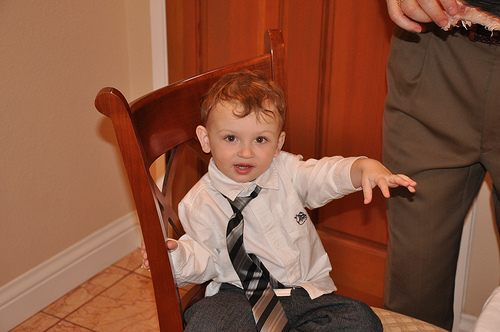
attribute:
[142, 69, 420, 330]
boy — posing, smiling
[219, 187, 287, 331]
tie — striped, black, silver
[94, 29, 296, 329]
chair — wooden, wood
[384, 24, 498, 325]
pants — khaki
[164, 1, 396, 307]
door — wood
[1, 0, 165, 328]
wall — beige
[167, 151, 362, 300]
shirt — white, long sleeved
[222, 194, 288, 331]
stripes — black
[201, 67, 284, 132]
hair — red, curled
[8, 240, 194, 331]
tile — large, brown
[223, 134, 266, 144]
eyes — black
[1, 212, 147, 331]
baseboard — white